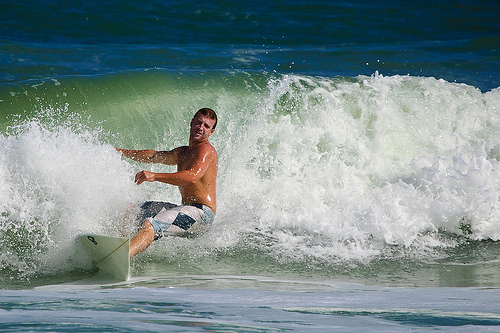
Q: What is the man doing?
A: Surfing.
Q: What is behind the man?
A: Wave.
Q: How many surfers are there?
A: One.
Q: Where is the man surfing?
A: Ocean.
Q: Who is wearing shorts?
A: The surfer.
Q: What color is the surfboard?
A: White.